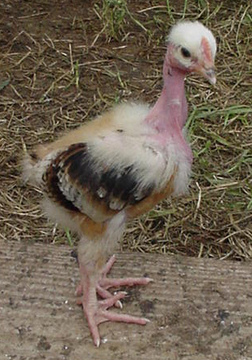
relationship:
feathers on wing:
[45, 136, 173, 220] [43, 142, 166, 213]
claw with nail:
[73, 252, 153, 347] [94, 336, 100, 348]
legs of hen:
[79, 226, 106, 306] [25, 20, 216, 347]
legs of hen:
[73, 252, 154, 306] [25, 20, 216, 347]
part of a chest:
[161, 158, 177, 181] [144, 151, 193, 217]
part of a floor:
[209, 307, 227, 330] [151, 257, 238, 352]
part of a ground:
[50, 306, 64, 344] [149, 252, 206, 340]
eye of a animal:
[178, 34, 193, 86] [20, 21, 216, 345]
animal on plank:
[20, 21, 216, 345] [0, 240, 249, 359]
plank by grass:
[0, 232, 250, 339] [87, 2, 134, 40]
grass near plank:
[26, 41, 132, 114] [1, 236, 241, 348]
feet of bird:
[75, 287, 148, 345] [96, 12, 215, 158]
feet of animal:
[75, 287, 148, 345] [20, 21, 216, 345]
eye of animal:
[178, 44, 192, 67] [20, 21, 216, 345]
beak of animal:
[200, 69, 219, 87] [20, 21, 216, 345]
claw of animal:
[74, 279, 148, 347] [20, 21, 216, 345]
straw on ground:
[225, 37, 246, 175] [1, 16, 161, 87]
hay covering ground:
[199, 99, 251, 179] [180, 203, 247, 260]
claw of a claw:
[78, 253, 155, 306] [77, 284, 156, 343]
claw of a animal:
[78, 253, 155, 306] [20, 21, 216, 345]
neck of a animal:
[157, 80, 191, 117] [20, 21, 216, 345]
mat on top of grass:
[167, 273, 209, 324] [27, 40, 123, 99]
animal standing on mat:
[20, 21, 216, 345] [134, 252, 251, 358]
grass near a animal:
[12, 33, 109, 98] [20, 21, 216, 345]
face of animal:
[168, 19, 218, 88] [20, 21, 216, 345]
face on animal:
[168, 19, 218, 88] [22, 21, 216, 345]